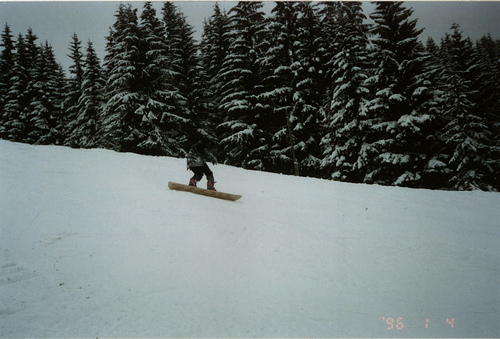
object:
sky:
[0, 1, 499, 81]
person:
[186, 140, 217, 190]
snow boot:
[206, 179, 214, 190]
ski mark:
[136, 210, 331, 268]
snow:
[3, 0, 500, 338]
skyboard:
[167, 181, 242, 202]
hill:
[0, 138, 500, 339]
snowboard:
[168, 181, 243, 202]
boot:
[189, 178, 197, 187]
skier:
[168, 134, 243, 202]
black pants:
[190, 164, 216, 182]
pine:
[0, 0, 500, 191]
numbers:
[379, 314, 475, 333]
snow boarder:
[187, 138, 218, 192]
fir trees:
[216, 19, 375, 182]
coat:
[186, 144, 218, 170]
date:
[382, 317, 456, 331]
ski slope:
[0, 140, 500, 339]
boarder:
[184, 131, 219, 190]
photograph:
[385, 313, 466, 330]